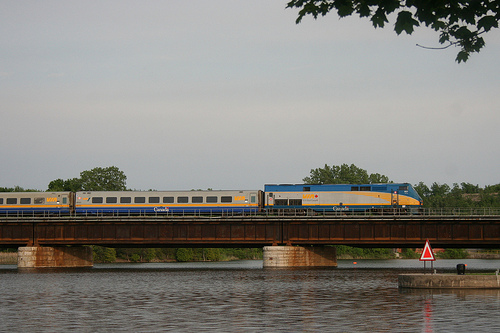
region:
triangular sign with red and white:
[416, 234, 436, 268]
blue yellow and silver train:
[2, 185, 427, 214]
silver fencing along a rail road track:
[5, 207, 465, 218]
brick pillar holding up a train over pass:
[17, 243, 104, 272]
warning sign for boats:
[417, 235, 437, 268]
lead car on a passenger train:
[262, 181, 425, 208]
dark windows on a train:
[87, 193, 232, 204]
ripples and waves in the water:
[162, 270, 238, 317]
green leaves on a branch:
[296, 7, 489, 77]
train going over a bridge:
[24, 170, 450, 277]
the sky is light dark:
[189, 60, 224, 88]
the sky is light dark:
[173, 44, 247, 129]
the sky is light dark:
[195, 24, 245, 115]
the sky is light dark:
[183, 12, 234, 99]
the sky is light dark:
[216, 35, 270, 100]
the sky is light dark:
[207, 68, 251, 128]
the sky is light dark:
[205, 50, 277, 144]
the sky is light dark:
[232, 90, 295, 121]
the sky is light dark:
[203, 54, 245, 75]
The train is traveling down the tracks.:
[0, 175, 495, 230]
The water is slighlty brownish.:
[65, 280, 376, 325]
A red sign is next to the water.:
[295, 230, 470, 321]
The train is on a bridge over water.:
[5, 156, 495, 277]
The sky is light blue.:
[50, 31, 380, 109]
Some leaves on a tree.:
[290, 6, 497, 67]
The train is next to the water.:
[15, 173, 497, 288]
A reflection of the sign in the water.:
[382, 225, 453, 331]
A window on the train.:
[87, 190, 99, 203]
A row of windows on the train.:
[87, 192, 235, 204]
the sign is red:
[426, 242, 429, 248]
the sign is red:
[423, 248, 435, 255]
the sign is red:
[427, 245, 434, 259]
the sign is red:
[420, 252, 434, 262]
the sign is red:
[420, 255, 427, 260]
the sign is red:
[426, 250, 433, 262]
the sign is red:
[421, 244, 430, 254]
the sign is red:
[421, 247, 432, 260]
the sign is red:
[423, 247, 435, 267]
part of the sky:
[256, 91, 260, 96]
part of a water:
[218, 265, 262, 318]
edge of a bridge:
[328, 195, 380, 232]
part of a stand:
[272, 245, 299, 261]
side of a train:
[316, 184, 371, 214]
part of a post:
[401, 216, 435, 268]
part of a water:
[258, 248, 297, 293]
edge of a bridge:
[256, 206, 299, 236]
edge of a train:
[406, 172, 418, 205]